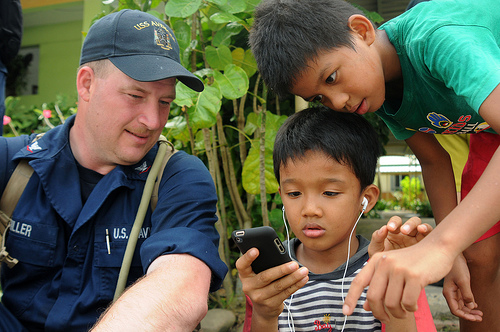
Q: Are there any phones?
A: Yes, there is a phone.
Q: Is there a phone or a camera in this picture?
A: Yes, there is a phone.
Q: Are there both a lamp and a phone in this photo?
A: No, there is a phone but no lamps.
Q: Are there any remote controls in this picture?
A: No, there are no remote controls.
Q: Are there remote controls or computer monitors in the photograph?
A: No, there are no remote controls or computer monitors.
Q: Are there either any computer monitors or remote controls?
A: No, there are no remote controls or computer monitors.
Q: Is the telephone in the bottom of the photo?
A: Yes, the telephone is in the bottom of the image.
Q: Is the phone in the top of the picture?
A: No, the phone is in the bottom of the image.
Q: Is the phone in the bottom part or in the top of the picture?
A: The phone is in the bottom of the image.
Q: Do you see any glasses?
A: No, there are no glasses.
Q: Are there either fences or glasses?
A: No, there are no glasses or fences.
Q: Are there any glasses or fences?
A: No, there are no glasses or fences.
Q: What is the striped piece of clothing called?
A: The clothing item is a shirt.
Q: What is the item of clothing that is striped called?
A: The clothing item is a shirt.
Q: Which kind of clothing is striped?
A: The clothing is a shirt.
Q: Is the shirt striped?
A: Yes, the shirt is striped.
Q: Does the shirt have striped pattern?
A: Yes, the shirt is striped.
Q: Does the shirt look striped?
A: Yes, the shirt is striped.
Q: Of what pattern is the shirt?
A: The shirt is striped.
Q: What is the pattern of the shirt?
A: The shirt is striped.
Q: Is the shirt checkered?
A: No, the shirt is striped.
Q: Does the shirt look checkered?
A: No, the shirt is striped.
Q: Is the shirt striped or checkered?
A: The shirt is striped.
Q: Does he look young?
A: Yes, the boy is young.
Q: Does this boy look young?
A: Yes, the boy is young.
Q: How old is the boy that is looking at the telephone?
A: The boy is young.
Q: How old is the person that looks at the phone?
A: The boy is young.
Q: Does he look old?
A: No, the boy is young.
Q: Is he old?
A: No, the boy is young.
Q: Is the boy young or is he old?
A: The boy is young.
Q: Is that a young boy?
A: Yes, that is a young boy.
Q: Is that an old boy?
A: No, that is a young boy.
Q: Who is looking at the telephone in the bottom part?
A: The boy is looking at the telephone.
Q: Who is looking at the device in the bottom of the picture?
A: The boy is looking at the telephone.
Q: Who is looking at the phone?
A: The boy is looking at the telephone.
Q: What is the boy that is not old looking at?
A: The boy is looking at the telephone.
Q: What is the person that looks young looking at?
A: The boy is looking at the telephone.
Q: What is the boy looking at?
A: The boy is looking at the telephone.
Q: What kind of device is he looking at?
A: The boy is looking at the phone.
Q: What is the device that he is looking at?
A: The device is a phone.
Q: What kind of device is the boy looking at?
A: The boy is looking at the phone.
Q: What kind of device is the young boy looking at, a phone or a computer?
A: The boy is looking at a phone.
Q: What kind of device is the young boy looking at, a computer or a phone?
A: The boy is looking at a phone.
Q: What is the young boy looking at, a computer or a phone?
A: The boy is looking at a phone.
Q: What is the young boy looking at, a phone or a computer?
A: The boy is looking at a phone.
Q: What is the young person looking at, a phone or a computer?
A: The boy is looking at a phone.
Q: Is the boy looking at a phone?
A: Yes, the boy is looking at a phone.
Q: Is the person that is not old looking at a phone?
A: Yes, the boy is looking at a phone.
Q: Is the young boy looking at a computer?
A: No, the boy is looking at a phone.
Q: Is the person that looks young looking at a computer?
A: No, the boy is looking at a phone.